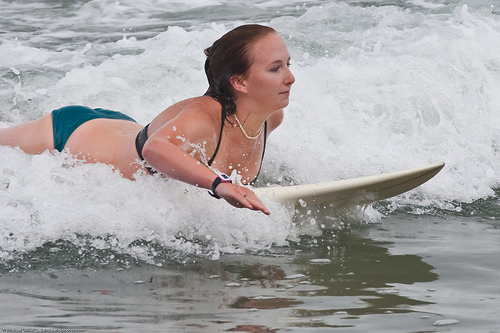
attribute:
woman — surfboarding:
[2, 13, 299, 218]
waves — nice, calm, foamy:
[4, 3, 493, 256]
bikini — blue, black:
[49, 101, 269, 191]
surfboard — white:
[240, 149, 449, 225]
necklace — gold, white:
[231, 102, 270, 147]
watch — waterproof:
[207, 169, 234, 201]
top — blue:
[134, 97, 275, 192]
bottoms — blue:
[41, 102, 136, 162]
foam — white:
[0, 21, 499, 262]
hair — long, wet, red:
[193, 23, 272, 112]